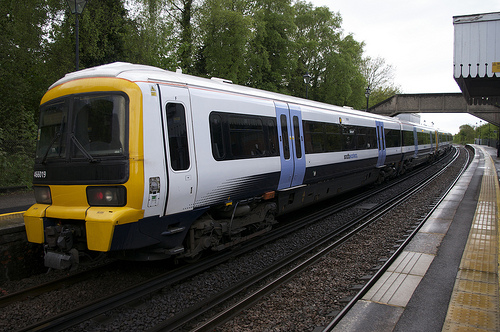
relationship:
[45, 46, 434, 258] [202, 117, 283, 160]
train has windows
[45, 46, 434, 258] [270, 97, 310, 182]
train has doors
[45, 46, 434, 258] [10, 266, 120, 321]
train has tracks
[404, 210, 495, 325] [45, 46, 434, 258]
platform by train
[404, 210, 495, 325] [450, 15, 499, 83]
platform has awning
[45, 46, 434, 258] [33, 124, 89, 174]
train has wipers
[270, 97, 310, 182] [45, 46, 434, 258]
doors on train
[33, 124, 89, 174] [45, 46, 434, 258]
wipers on train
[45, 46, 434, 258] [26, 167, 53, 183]
train has number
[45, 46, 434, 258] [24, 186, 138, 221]
train has headlights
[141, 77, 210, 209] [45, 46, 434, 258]
door on train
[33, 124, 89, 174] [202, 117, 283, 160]
wipers on windows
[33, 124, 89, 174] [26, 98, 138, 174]
wipers on windshield